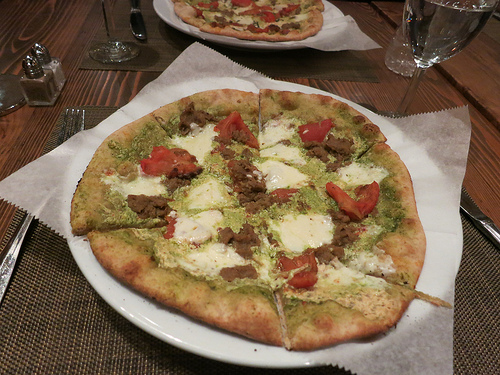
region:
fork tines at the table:
[48, 103, 88, 143]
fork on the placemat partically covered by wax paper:
[2, 104, 84, 316]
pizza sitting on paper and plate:
[66, 87, 437, 351]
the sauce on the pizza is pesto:
[85, 85, 428, 360]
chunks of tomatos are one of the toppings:
[323, 181, 392, 221]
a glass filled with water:
[392, 0, 495, 117]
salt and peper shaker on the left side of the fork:
[21, 40, 70, 109]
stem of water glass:
[83, 0, 143, 69]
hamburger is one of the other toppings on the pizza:
[123, 194, 180, 217]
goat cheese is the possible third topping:
[81, 93, 429, 343]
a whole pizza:
[72, 86, 425, 351]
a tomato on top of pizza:
[215, 110, 255, 140]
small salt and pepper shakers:
[20, 36, 60, 98]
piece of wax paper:
[5, 35, 465, 370]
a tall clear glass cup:
[371, 0, 492, 125]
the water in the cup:
[404, 1, 488, 64]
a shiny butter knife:
[455, 181, 497, 241]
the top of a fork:
[56, 105, 86, 135]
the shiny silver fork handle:
[0, 210, 30, 306]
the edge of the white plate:
[70, 335, 313, 366]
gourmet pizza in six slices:
[71, 76, 443, 351]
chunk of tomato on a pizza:
[278, 246, 328, 293]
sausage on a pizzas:
[214, 218, 260, 253]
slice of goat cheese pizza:
[252, 221, 417, 348]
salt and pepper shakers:
[17, 36, 67, 110]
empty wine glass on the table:
[400, 6, 490, 143]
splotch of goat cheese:
[269, 211, 336, 258]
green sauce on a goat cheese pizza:
[124, 118, 166, 149]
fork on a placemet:
[3, 99, 88, 304]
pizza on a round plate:
[66, 83, 467, 367]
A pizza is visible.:
[135, 125, 347, 365]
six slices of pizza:
[91, 100, 453, 356]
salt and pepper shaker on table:
[11, 44, 75, 109]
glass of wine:
[383, 3, 491, 126]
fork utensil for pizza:
[3, 115, 83, 338]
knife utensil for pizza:
[393, 99, 499, 281]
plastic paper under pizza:
[7, 49, 491, 374]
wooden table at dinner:
[0, 2, 497, 113]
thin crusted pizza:
[70, 75, 430, 350]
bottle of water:
[360, 0, 440, 91]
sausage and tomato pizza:
[95, 73, 455, 359]